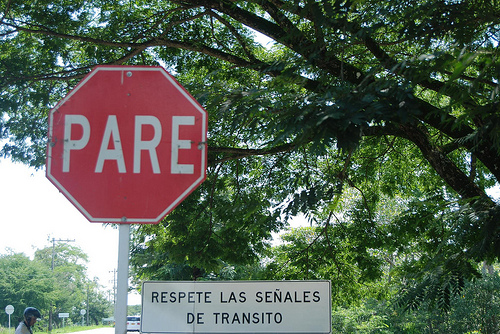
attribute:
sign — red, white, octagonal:
[45, 65, 208, 225]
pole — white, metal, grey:
[114, 222, 136, 333]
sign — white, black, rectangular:
[138, 278, 337, 332]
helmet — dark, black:
[25, 307, 43, 322]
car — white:
[125, 311, 142, 333]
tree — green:
[206, 0, 498, 329]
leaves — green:
[286, 71, 400, 148]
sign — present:
[55, 309, 74, 322]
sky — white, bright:
[0, 166, 120, 284]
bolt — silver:
[123, 67, 135, 81]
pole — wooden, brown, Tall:
[41, 227, 77, 333]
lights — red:
[135, 322, 141, 328]